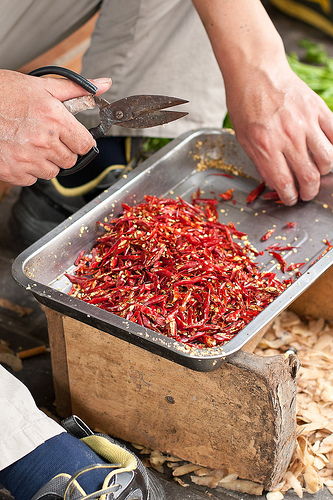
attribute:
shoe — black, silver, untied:
[48, 415, 155, 499]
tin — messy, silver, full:
[21, 117, 324, 356]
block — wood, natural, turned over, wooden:
[56, 308, 310, 486]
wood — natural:
[247, 354, 289, 500]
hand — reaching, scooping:
[226, 68, 331, 193]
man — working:
[2, 3, 332, 205]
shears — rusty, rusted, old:
[69, 88, 187, 143]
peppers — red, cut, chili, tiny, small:
[143, 214, 242, 294]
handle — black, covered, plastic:
[32, 59, 100, 92]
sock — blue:
[14, 432, 99, 493]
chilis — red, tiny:
[71, 258, 105, 314]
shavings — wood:
[295, 330, 333, 480]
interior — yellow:
[94, 437, 129, 466]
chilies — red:
[207, 242, 239, 288]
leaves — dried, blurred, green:
[293, 38, 332, 94]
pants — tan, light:
[4, 0, 234, 135]